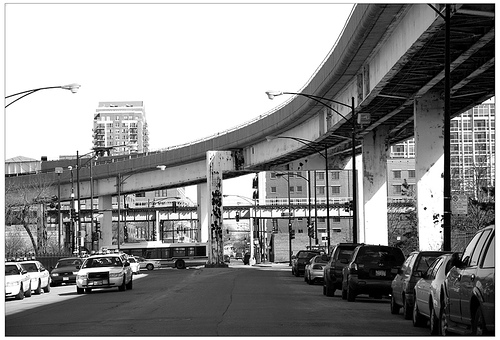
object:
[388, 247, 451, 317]
car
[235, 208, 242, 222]
traffic light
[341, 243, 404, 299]
vehicle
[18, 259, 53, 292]
car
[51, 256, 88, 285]
car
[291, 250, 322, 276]
car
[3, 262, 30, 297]
vehicle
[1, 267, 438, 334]
street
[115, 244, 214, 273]
bus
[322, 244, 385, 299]
car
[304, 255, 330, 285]
car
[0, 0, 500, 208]
overpass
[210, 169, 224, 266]
graffiti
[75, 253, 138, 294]
car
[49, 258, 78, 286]
car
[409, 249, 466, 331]
car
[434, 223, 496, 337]
car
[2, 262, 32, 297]
police cars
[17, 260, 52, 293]
police cars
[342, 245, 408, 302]
car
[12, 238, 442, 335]
road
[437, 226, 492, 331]
parked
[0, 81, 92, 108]
street light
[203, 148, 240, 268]
column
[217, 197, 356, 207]
guard rail